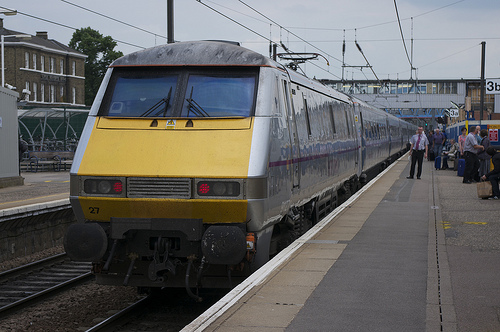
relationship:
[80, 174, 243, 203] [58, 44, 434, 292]
headlight on train